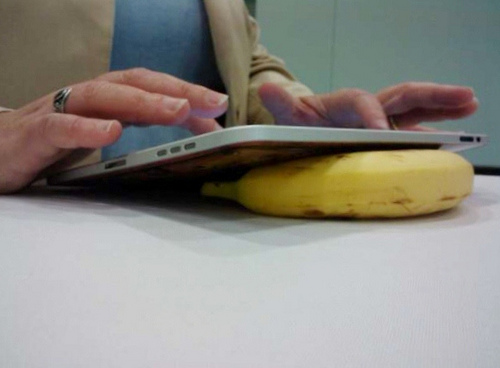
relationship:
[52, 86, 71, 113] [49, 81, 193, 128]
ring on finger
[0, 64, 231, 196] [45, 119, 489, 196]
hand using tablet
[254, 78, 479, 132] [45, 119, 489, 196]
hand on tablet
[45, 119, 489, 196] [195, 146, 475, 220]
tablet propped up on banana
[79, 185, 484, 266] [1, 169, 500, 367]
shadow of tablet on table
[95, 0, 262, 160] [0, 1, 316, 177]
shirt under jacket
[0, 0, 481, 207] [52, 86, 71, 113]
person wearing ring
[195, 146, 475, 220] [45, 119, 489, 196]
banana under tablet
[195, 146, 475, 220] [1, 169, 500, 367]
banana on table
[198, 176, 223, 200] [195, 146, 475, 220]
tip of banana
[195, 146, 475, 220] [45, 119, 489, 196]
banana supporting tablet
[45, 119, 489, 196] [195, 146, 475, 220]
tablet resting on banana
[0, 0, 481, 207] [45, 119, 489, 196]
person using tablet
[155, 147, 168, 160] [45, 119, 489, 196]
button on tablet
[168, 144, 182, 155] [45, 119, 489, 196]
button on tablet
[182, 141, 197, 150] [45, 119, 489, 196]
button on tablet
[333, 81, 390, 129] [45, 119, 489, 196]
finger tapping tablet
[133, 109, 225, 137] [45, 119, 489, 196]
finger tapping tablet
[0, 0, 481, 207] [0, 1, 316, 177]
person wearing jacket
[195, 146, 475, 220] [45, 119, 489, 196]
banana underneath tablet